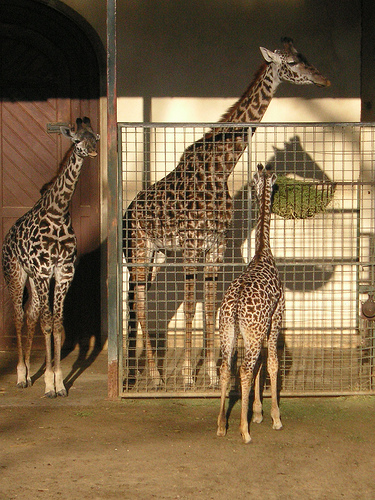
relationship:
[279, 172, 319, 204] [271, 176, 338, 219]
hay in bucket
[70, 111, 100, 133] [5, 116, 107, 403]
horns on giraffe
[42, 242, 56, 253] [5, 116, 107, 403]
spot on giraffe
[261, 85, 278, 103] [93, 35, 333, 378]
spot on giraffe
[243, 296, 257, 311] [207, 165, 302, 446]
spot on giraffe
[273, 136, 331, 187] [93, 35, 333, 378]
shadow of giraffe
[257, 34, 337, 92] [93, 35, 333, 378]
head of giraffe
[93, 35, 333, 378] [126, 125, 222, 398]
giraffe behind fence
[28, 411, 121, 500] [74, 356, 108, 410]
dirt on floor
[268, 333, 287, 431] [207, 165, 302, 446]
leg on giraffe